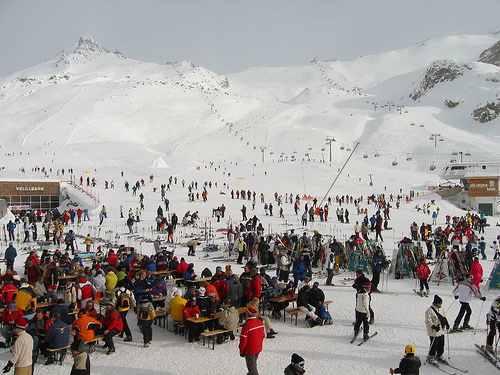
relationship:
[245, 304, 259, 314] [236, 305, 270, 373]
head of a man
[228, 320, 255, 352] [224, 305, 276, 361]
arm of a man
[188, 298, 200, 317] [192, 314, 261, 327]
person sitting at table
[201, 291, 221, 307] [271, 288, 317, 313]
person sitting at table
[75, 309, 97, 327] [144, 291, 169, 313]
person sitting at table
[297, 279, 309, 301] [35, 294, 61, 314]
person sitting at table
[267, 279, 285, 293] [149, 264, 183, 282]
person sitting at table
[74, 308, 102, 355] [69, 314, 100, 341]
man wearing jacket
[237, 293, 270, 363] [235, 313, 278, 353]
man wearing jacket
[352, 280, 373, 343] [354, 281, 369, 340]
man wearing jacket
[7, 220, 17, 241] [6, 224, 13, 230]
person wearing blue jacket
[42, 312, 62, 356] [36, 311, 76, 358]
person wearing jacket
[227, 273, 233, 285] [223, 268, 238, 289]
person wearing blue jacket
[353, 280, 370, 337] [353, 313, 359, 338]
man has leg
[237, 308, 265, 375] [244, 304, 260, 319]
man wearing a hat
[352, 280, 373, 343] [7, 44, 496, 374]
man in snow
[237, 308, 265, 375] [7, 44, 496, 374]
man in snow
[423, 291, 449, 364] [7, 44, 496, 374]
man in snow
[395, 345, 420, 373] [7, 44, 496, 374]
people in snow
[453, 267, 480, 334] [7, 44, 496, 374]
people in snow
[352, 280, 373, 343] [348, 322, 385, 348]
man on skis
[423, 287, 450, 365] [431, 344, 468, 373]
man on skis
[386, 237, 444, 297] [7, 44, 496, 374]
people on snow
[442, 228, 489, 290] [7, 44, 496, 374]
people on snow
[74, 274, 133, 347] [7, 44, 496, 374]
people on snow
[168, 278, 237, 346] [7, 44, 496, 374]
people on snow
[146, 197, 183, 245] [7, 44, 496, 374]
people on snow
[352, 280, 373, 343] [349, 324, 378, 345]
man on skis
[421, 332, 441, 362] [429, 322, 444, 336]
ski pole on hand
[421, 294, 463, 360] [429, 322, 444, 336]
person has hand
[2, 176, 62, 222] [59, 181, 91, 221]
brick building in snow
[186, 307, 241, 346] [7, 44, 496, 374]
picnic table in snow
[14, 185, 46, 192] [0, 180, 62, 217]
writing in front of building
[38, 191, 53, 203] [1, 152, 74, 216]
window in front of building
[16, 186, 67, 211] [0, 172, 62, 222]
windows are on brick building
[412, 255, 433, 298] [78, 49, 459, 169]
people at slope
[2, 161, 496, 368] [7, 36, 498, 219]
people at slope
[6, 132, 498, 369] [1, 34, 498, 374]
people at ski slope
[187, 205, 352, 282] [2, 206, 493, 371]
crowd at slope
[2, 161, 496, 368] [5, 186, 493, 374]
people at slope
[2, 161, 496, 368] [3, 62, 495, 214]
people at ski slope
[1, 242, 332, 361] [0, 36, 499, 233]
crowd people at slopes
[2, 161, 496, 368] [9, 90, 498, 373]
people at slope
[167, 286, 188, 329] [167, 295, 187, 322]
person wearing jacket